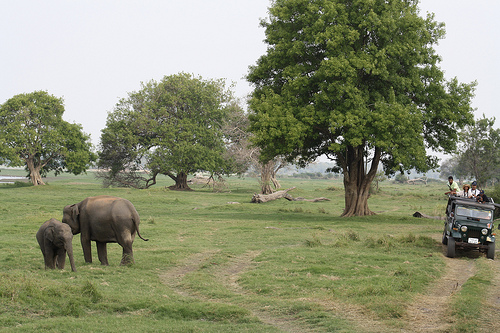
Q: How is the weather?
A: It is clear.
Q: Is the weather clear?
A: Yes, it is clear.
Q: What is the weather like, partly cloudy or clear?
A: It is clear.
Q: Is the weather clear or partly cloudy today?
A: It is clear.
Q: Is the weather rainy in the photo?
A: No, it is clear.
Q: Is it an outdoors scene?
A: Yes, it is outdoors.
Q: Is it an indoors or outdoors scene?
A: It is outdoors.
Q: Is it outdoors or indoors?
A: It is outdoors.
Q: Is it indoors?
A: No, it is outdoors.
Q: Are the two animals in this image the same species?
A: Yes, all the animals are elephants.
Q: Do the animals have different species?
A: No, all the animals are elephants.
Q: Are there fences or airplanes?
A: No, there are no fences or airplanes.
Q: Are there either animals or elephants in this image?
A: Yes, there is an elephant.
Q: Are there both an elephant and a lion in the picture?
A: No, there is an elephant but no lions.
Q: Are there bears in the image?
A: No, there are no bears.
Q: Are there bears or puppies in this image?
A: No, there are no bears or puppies.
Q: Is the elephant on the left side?
A: Yes, the elephant is on the left of the image.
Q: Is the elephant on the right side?
A: No, the elephant is on the left of the image.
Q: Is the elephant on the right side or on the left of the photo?
A: The elephant is on the left of the image.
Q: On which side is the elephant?
A: The elephant is on the left of the image.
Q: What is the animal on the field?
A: The animal is an elephant.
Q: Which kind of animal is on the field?
A: The animal is an elephant.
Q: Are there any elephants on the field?
A: Yes, there is an elephant on the field.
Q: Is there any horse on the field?
A: No, there is an elephant on the field.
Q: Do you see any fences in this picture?
A: No, there are no fences.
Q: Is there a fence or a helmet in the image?
A: No, there are no fences or helmets.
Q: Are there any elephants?
A: Yes, there is an elephant.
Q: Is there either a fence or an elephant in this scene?
A: Yes, there is an elephant.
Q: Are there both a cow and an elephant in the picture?
A: No, there is an elephant but no cows.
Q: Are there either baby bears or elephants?
A: Yes, there is a baby elephant.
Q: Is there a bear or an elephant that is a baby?
A: Yes, the elephant is a baby.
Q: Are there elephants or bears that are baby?
A: Yes, the elephant is a baby.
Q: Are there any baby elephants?
A: Yes, there is a baby elephant.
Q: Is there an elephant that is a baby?
A: Yes, there is an elephant that is a baby.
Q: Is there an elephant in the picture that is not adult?
A: Yes, there is an baby elephant.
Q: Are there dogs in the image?
A: No, there are no dogs.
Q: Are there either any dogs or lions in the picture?
A: No, there are no dogs or lions.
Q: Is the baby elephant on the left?
A: Yes, the elephant is on the left of the image.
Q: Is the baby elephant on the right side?
A: No, the elephant is on the left of the image.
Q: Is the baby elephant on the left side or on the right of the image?
A: The elephant is on the left of the image.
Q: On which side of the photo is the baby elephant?
A: The elephant is on the left of the image.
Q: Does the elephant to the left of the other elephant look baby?
A: Yes, the elephant is a baby.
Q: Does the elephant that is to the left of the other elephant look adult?
A: No, the elephant is a baby.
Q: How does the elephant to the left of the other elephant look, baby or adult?
A: The elephant is a baby.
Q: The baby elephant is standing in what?
A: The elephant is standing in the grass.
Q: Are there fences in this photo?
A: No, there are no fences.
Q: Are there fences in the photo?
A: No, there are no fences.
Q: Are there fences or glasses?
A: No, there are no fences or glasses.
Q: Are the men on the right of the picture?
A: Yes, the men are on the right of the image.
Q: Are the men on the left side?
A: No, the men are on the right of the image.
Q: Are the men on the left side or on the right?
A: The men are on the right of the image.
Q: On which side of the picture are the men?
A: The men are on the right of the image.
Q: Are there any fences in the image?
A: No, there are no fences.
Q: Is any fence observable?
A: No, there are no fences.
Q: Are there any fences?
A: No, there are no fences.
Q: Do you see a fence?
A: No, there are no fences.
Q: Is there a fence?
A: No, there are no fences.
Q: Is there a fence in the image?
A: No, there are no fences.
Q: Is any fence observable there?
A: No, there are no fences.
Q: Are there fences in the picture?
A: No, there are no fences.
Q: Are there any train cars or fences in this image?
A: No, there are no fences or train cars.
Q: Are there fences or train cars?
A: No, there are no fences or train cars.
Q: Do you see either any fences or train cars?
A: No, there are no fences or train cars.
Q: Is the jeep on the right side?
A: Yes, the jeep is on the right of the image.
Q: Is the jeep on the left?
A: No, the jeep is on the right of the image.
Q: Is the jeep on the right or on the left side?
A: The jeep is on the right of the image.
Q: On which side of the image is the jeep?
A: The jeep is on the right of the image.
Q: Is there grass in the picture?
A: Yes, there is grass.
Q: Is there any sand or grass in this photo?
A: Yes, there is grass.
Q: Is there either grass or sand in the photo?
A: Yes, there is grass.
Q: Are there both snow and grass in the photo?
A: No, there is grass but no snow.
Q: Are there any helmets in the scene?
A: No, there are no helmets.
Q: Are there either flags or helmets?
A: No, there are no helmets or flags.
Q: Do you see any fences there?
A: No, there are no fences.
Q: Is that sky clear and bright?
A: Yes, the sky is clear and bright.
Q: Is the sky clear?
A: Yes, the sky is clear.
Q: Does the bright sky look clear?
A: Yes, the sky is clear.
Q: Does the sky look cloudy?
A: No, the sky is clear.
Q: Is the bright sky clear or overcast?
A: The sky is clear.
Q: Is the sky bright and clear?
A: Yes, the sky is bright and clear.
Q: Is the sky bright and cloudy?
A: No, the sky is bright but clear.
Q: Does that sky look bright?
A: Yes, the sky is bright.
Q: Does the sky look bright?
A: Yes, the sky is bright.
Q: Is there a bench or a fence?
A: No, there are no fences or benches.